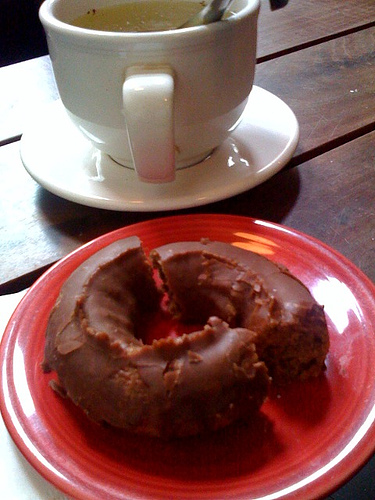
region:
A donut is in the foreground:
[32, 230, 333, 442]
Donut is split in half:
[33, 227, 352, 438]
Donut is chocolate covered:
[36, 227, 345, 437]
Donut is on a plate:
[1, 211, 372, 499]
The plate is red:
[0, 207, 374, 495]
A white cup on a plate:
[14, 1, 317, 215]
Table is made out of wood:
[0, 19, 373, 246]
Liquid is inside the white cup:
[62, 5, 239, 44]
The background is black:
[0, 1, 45, 67]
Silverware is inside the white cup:
[175, 0, 244, 32]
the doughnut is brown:
[32, 212, 333, 428]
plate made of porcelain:
[6, 214, 356, 495]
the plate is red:
[0, 215, 370, 490]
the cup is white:
[30, 1, 272, 147]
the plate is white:
[15, 61, 296, 205]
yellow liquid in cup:
[75, 2, 243, 64]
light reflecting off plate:
[30, 79, 286, 199]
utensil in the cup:
[172, 2, 243, 43]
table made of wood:
[0, 1, 369, 496]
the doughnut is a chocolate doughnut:
[38, 218, 336, 435]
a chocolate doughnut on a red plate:
[14, 217, 349, 482]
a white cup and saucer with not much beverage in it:
[10, 8, 319, 210]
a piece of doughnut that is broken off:
[157, 231, 333, 377]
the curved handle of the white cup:
[112, 72, 190, 188]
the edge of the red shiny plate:
[276, 218, 371, 292]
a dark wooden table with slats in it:
[280, 18, 371, 209]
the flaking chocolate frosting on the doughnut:
[153, 336, 248, 385]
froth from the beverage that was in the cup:
[78, 9, 179, 34]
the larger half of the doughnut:
[42, 244, 216, 459]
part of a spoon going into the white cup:
[182, 1, 239, 31]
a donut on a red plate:
[0, 223, 370, 477]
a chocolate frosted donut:
[30, 233, 334, 379]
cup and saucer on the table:
[7, 0, 352, 250]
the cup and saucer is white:
[6, 0, 297, 196]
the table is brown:
[259, 0, 364, 165]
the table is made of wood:
[255, 0, 346, 158]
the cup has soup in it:
[32, 0, 227, 51]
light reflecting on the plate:
[285, 241, 360, 333]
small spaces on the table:
[295, 15, 357, 165]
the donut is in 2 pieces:
[61, 221, 332, 426]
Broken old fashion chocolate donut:
[34, 231, 330, 452]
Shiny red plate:
[0, 211, 371, 498]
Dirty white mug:
[37, 0, 263, 185]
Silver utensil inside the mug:
[162, 0, 239, 38]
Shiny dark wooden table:
[1, 1, 373, 328]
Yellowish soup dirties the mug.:
[65, 2, 242, 37]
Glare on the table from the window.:
[0, 44, 57, 496]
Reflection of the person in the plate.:
[301, 262, 372, 392]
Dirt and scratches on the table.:
[287, 70, 368, 199]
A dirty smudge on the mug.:
[168, 137, 188, 162]